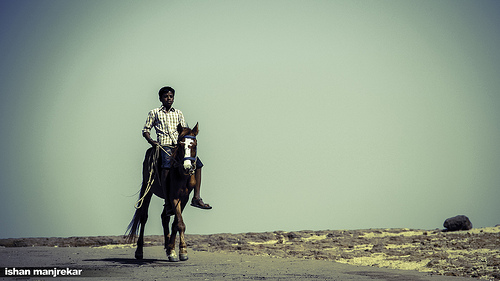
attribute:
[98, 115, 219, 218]
horse — walking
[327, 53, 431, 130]
sky — white, grey, blue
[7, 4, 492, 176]
sky — blue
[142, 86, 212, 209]
boy — young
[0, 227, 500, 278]
terrain — flat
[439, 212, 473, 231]
rock — large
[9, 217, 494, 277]
ground — brown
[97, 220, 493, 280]
brush — yellow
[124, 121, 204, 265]
horse — small, brown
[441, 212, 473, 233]
stone — single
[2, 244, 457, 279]
road — paved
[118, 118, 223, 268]
horse — brown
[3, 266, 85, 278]
name — person's, white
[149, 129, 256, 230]
horse — brown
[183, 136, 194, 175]
blaze — white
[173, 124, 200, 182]
face — white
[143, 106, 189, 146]
shirt — striped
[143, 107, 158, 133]
sleeve — long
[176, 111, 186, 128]
sleeve — long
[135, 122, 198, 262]
horse — taking steps